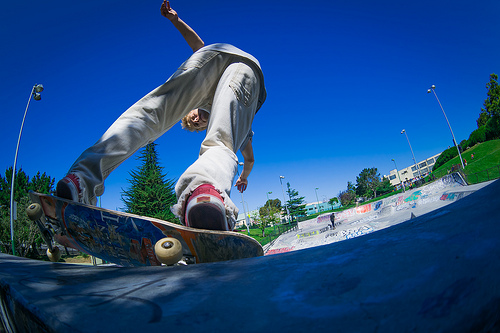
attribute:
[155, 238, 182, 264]
wheel — yellow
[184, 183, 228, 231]
shoe — red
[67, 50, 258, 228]
jeans — beige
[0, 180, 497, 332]
wall — large, concrete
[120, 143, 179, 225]
tree — large, tall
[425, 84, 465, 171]
pole — tall, light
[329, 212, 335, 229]
skater — standing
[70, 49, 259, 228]
pants — white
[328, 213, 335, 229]
person — standing, skateboarding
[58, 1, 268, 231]
man — skateboarding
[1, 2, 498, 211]
sky — blue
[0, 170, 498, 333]
ramp — concrete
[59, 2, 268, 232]
guy — looking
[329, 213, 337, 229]
clothing — dark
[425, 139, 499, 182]
hill — green